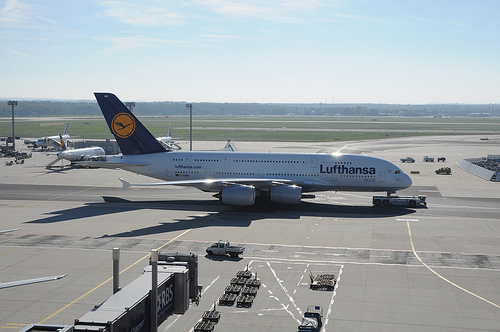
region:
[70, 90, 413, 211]
a blue and white jet airplane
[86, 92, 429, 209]
an airplane being pulled by a vehicle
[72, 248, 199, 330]
an airplane boarding walkway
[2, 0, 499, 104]
a cloudy blue sky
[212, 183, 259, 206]
an airplane jet engine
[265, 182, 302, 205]
an airplane jet engine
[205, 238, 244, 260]
a white pickup truck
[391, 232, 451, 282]
curved white line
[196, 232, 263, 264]
white truck on tarmac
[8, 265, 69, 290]
white wing on the side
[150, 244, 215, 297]
tall gray ramp over vehicle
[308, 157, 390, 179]
name on side of plane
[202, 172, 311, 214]
silver wings on side of plane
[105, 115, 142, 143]
blue bird in yellow ring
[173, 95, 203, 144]
tall silver light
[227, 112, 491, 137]
long runway in the distance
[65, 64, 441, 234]
a plane parked at the airport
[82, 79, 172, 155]
tailwing of the plane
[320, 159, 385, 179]
plane logo on it's side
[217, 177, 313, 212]
two turbines on the plane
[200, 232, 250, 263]
a white truck at the airport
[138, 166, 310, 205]
wing of the plane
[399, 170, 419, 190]
nose of the plane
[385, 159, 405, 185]
cockpit of the plane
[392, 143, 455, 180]
cars that are parked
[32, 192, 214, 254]
the planes shadow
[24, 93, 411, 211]
airplanes at airport on ground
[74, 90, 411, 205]
large white airplane being taxied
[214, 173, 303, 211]
turbine engines on plane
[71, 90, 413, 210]
airplane is white, blue, and gold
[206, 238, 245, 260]
white truck driving by plane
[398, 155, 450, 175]
vehicles waiting beside plane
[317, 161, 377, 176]
Airplane says LUFTHANSA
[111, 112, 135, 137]
orange circle on tail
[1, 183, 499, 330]
orange painted lines on runway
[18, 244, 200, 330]
terminal arm waiting to attach to plane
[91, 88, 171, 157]
the gold and blue tail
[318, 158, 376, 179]
the word on side of plane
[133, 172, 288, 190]
the wing on plane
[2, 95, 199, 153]
the light poles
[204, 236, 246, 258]
the white truck on tarmac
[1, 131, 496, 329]
the parking lot of planes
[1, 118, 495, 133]
the runway for planes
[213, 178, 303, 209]
the engines on the plane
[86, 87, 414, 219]
the huge plane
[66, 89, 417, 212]
large plane on the airway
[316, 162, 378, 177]
word in blue on the plane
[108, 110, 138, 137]
yellow logo on the plane's tail